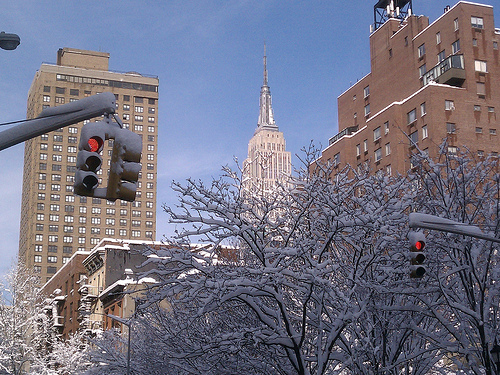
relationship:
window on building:
[404, 106, 421, 128] [295, 3, 499, 231]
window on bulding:
[404, 106, 416, 126] [298, 8, 498, 215]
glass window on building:
[398, 46, 467, 155] [302, 14, 487, 183]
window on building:
[366, 114, 428, 166] [303, 30, 479, 175]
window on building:
[384, 139, 401, 162] [309, 23, 479, 191]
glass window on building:
[380, 149, 388, 158] [309, 23, 479, 191]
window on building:
[32, 219, 49, 234] [19, 43, 152, 270]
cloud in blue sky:
[155, 146, 241, 181] [0, 0, 498, 298]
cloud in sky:
[155, 146, 245, 181] [1, 0, 498, 306]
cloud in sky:
[0, 105, 26, 295] [1, 0, 498, 306]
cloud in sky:
[168, 2, 237, 37] [1, 0, 498, 306]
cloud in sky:
[155, 146, 241, 181] [0, 1, 489, 226]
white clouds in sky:
[238, 10, 311, 30] [201, 19, 291, 56]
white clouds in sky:
[162, 31, 240, 86] [306, 45, 360, 80]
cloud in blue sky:
[155, 146, 241, 181] [157, 0, 378, 67]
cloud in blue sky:
[0, 105, 23, 295] [157, 0, 378, 67]